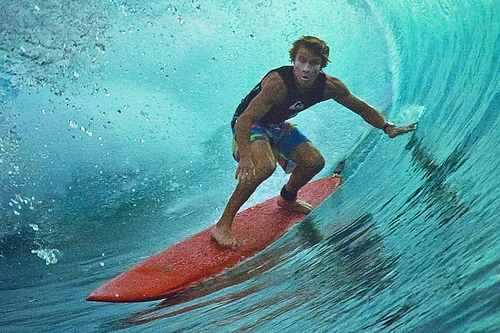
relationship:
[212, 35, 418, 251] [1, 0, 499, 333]
man riding wave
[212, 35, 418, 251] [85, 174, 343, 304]
man on top of surfboard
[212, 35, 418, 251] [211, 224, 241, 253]
man has foot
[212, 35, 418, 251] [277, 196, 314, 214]
man has foot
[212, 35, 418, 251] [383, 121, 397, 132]
man wears watch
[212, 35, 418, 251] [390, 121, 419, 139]
man has hand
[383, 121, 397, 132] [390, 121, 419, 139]
watch above hand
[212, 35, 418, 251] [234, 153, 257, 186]
man has hand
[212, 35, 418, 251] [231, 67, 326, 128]
man wearing shirt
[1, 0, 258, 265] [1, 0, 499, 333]
ocean spray from wave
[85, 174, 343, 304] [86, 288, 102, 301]
surfboard has tip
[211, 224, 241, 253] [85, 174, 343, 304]
foot on surfboard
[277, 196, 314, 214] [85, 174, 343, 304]
foot on surfboard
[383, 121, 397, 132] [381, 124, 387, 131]
watch has strap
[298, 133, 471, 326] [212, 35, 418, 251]
shadow of man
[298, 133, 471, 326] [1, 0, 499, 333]
shadow reflecting on wave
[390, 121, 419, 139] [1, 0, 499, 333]
hand touching wave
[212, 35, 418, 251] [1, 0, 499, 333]
man inside wave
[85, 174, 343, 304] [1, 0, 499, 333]
surfboard on top of wave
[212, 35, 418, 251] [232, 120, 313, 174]
man wearing swim trunks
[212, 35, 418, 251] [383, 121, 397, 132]
man wearing watch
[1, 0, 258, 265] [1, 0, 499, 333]
ocean spray splashing from wave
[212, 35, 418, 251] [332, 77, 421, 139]
man has arm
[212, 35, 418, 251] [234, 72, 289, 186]
man has arm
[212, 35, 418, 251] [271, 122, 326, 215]
man has leg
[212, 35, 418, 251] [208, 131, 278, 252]
man has leg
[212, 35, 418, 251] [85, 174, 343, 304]
man riding surfboard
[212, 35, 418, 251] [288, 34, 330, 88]
man has head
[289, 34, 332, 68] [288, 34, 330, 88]
hair blowing on head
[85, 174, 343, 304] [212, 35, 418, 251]
surfboard underneath man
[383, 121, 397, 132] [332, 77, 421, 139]
watch worn on arm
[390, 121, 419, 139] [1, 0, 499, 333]
hand inside wave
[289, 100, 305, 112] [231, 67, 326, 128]
design printed on shirt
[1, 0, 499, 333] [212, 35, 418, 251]
wave surrounds man